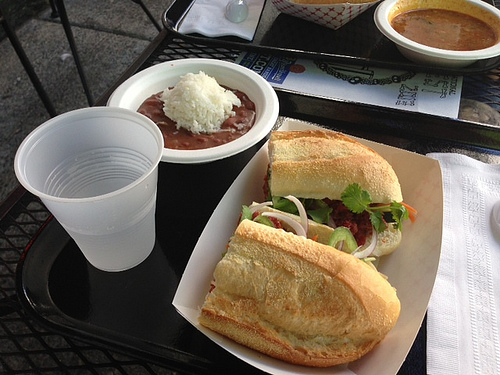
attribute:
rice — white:
[158, 67, 239, 132]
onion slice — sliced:
[285, 191, 308, 231]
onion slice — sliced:
[259, 210, 307, 237]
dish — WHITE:
[375, 3, 499, 84]